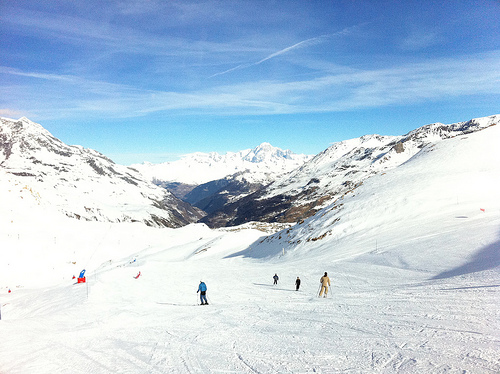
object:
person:
[316, 271, 331, 299]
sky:
[0, 0, 497, 163]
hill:
[0, 117, 203, 226]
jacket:
[196, 282, 208, 292]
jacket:
[319, 276, 331, 285]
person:
[294, 276, 301, 291]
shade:
[154, 172, 343, 262]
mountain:
[193, 112, 500, 264]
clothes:
[294, 278, 300, 285]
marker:
[78, 269, 86, 284]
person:
[272, 273, 280, 287]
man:
[271, 273, 280, 284]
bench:
[77, 276, 86, 283]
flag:
[79, 269, 87, 278]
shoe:
[200, 301, 205, 305]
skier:
[196, 279, 210, 306]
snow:
[0, 103, 498, 372]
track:
[234, 351, 261, 374]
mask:
[324, 272, 329, 277]